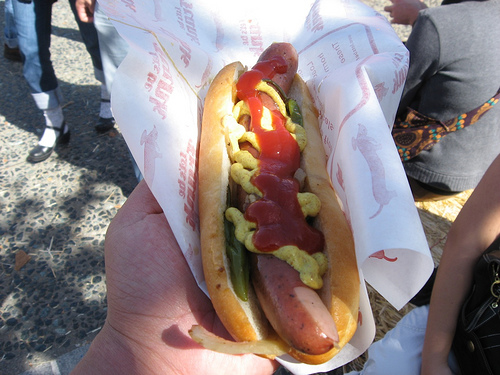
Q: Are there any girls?
A: No, there are no girls.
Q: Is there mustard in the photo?
A: Yes, there is mustard.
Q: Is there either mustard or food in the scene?
A: Yes, there is mustard.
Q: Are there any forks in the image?
A: No, there are no forks.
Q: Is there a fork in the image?
A: No, there are no forks.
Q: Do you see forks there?
A: No, there are no forks.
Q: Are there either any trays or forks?
A: No, there are no forks or trays.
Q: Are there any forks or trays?
A: No, there are no forks or trays.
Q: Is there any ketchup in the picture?
A: Yes, there is ketchup.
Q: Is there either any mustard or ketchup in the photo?
A: Yes, there is ketchup.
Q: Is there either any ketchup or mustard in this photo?
A: Yes, there is ketchup.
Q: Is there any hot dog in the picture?
A: Yes, there is a hot dog.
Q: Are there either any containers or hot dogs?
A: Yes, there is a hot dog.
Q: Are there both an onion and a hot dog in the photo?
A: Yes, there are both a hot dog and an onion.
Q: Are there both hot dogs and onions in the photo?
A: Yes, there are both a hot dog and an onion.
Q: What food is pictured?
A: The food is a hot dog.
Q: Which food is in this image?
A: The food is a hot dog.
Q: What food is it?
A: The food is a hot dog.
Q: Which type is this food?
A: This is a hot dog.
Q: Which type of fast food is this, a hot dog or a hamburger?
A: This is a hot dog.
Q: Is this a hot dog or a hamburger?
A: This is a hot dog.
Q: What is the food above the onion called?
A: The food is a hot dog.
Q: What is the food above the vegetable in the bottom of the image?
A: The food is a hot dog.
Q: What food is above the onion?
A: The food is a hot dog.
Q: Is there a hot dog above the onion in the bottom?
A: Yes, there is a hot dog above the onion.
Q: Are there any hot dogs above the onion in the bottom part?
A: Yes, there is a hot dog above the onion.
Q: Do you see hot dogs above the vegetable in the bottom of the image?
A: Yes, there is a hot dog above the onion.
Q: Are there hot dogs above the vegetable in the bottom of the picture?
A: Yes, there is a hot dog above the onion.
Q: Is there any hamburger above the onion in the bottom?
A: No, there is a hot dog above the onion.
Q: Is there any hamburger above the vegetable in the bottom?
A: No, there is a hot dog above the onion.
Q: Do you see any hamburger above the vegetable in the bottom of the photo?
A: No, there is a hot dog above the onion.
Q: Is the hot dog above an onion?
A: Yes, the hot dog is above an onion.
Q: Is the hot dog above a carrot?
A: No, the hot dog is above an onion.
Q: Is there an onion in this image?
A: Yes, there is an onion.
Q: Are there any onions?
A: Yes, there is an onion.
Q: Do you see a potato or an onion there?
A: Yes, there is an onion.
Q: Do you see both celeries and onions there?
A: No, there is an onion but no celeries.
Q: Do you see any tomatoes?
A: No, there are no tomatoes.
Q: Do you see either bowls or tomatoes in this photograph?
A: No, there are no tomatoes or bowls.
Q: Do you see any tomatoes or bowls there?
A: No, there are no tomatoes or bowls.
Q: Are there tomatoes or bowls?
A: No, there are no tomatoes or bowls.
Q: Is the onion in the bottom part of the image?
A: Yes, the onion is in the bottom of the image.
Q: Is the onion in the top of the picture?
A: No, the onion is in the bottom of the image.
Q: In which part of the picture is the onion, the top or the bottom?
A: The onion is in the bottom of the image.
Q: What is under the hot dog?
A: The onion is under the hot dog.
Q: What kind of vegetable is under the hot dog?
A: The vegetable is an onion.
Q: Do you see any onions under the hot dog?
A: Yes, there is an onion under the hot dog.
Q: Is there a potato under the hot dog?
A: No, there is an onion under the hot dog.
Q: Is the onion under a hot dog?
A: Yes, the onion is under a hot dog.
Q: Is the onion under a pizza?
A: No, the onion is under a hot dog.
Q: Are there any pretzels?
A: No, there are no pretzels.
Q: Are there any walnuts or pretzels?
A: No, there are no pretzels or walnuts.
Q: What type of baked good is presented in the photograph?
A: The baked good is a bun.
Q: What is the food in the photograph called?
A: The food is a bun.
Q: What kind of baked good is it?
A: The food is a bun.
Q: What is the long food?
A: The food is a bun.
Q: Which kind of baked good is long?
A: The baked good is a bun.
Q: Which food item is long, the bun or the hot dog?
A: The bun is long.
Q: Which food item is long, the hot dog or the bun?
A: The bun is long.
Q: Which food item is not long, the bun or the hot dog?
A: The hot dog is not long.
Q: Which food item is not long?
A: The food item is a hot dog.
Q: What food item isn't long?
A: The food item is a hot dog.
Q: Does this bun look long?
A: Yes, the bun is long.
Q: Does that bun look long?
A: Yes, the bun is long.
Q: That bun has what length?
A: The bun is long.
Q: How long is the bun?
A: The bun is long.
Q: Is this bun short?
A: No, the bun is long.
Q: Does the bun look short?
A: No, the bun is long.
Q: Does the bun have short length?
A: No, the bun is long.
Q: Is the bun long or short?
A: The bun is long.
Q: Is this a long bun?
A: Yes, this is a long bun.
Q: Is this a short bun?
A: No, this is a long bun.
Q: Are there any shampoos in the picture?
A: No, there are no shampoos.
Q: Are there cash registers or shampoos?
A: No, there are no shampoos or cash registers.